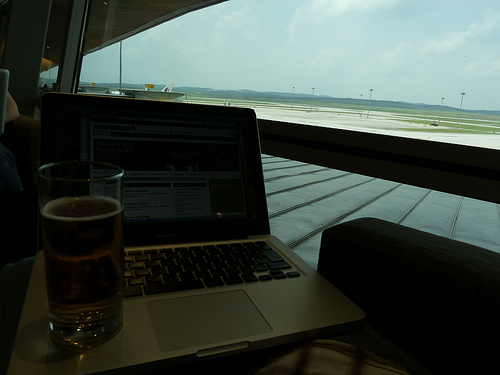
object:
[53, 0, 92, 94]
beam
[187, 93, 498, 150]
field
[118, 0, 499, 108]
cloud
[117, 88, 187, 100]
boat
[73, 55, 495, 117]
distance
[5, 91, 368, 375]
computer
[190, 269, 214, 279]
key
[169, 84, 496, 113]
hill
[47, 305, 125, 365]
light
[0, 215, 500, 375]
chair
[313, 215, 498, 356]
arm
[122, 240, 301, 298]
key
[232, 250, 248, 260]
key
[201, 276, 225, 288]
key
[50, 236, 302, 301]
keyboard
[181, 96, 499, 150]
runway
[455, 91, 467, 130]
pole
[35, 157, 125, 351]
glass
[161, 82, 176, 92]
tail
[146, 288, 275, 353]
track pad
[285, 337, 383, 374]
plaid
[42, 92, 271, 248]
screen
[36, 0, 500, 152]
airport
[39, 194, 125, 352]
beer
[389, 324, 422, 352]
material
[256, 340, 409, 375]
lap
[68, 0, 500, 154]
window